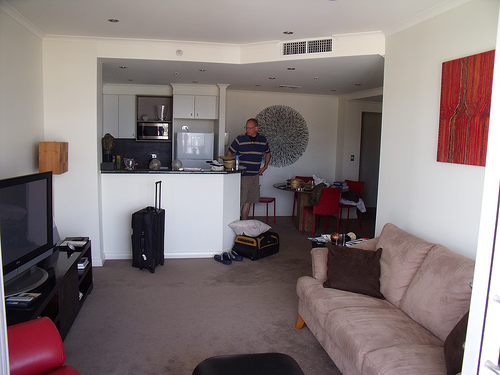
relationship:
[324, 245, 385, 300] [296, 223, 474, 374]
pillow on couch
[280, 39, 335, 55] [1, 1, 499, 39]
vent on ceiling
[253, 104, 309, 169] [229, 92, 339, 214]
decoration on wall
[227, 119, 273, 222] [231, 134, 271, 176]
man wearing a shirt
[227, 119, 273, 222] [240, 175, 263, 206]
man wearing shorts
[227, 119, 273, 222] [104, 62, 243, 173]
man near kitchen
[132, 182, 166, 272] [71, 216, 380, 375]
suitcase on floor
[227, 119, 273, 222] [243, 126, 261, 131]
man wearing glasses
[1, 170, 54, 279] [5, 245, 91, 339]
television on entertainment center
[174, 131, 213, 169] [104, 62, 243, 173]
refrigerator in kitchen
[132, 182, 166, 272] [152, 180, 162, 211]
suitcase has a handle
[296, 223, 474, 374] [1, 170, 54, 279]
couch in front of television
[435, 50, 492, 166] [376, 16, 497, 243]
artwork on wall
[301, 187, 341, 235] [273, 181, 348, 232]
chair at table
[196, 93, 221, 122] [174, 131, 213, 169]
cabinet above refrigerator